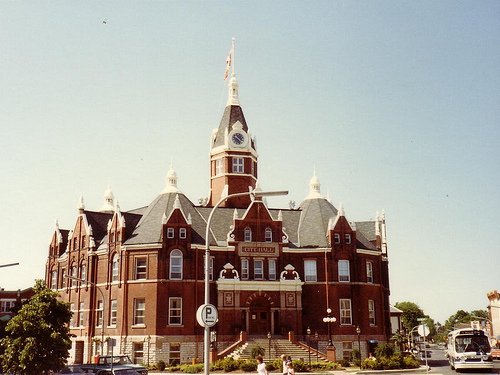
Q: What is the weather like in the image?
A: It is cloudless.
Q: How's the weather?
A: It is cloudless.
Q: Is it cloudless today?
A: Yes, it is cloudless.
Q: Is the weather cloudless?
A: Yes, it is cloudless.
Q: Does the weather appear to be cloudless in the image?
A: Yes, it is cloudless.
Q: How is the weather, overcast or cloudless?
A: It is cloudless.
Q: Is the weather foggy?
A: No, it is cloudless.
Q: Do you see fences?
A: No, there are no fences.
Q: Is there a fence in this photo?
A: No, there are no fences.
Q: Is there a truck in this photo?
A: Yes, there is a truck.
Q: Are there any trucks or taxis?
A: Yes, there is a truck.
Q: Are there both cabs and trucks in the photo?
A: No, there is a truck but no taxis.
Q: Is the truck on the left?
A: Yes, the truck is on the left of the image.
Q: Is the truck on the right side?
A: No, the truck is on the left of the image.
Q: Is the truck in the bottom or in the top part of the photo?
A: The truck is in the bottom of the image.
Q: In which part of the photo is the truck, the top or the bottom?
A: The truck is in the bottom of the image.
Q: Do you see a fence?
A: No, there are no fences.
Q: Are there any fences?
A: No, there are no fences.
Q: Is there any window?
A: Yes, there is a window.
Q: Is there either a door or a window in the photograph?
A: Yes, there is a window.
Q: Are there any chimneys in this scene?
A: No, there are no chimneys.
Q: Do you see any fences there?
A: No, there are no fences.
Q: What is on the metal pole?
A: The sign is on the pole.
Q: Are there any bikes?
A: No, there are no bikes.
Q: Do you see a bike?
A: No, there are no bikes.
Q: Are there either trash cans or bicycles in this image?
A: No, there are no bicycles or trash cans.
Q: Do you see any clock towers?
A: Yes, there is a clock tower.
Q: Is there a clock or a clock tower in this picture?
A: Yes, there is a clock tower.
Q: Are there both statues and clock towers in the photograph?
A: No, there is a clock tower but no statues.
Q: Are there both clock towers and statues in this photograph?
A: No, there is a clock tower but no statues.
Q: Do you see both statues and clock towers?
A: No, there is a clock tower but no statues.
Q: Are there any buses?
A: Yes, there is a bus.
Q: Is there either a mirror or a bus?
A: Yes, there is a bus.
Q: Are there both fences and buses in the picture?
A: No, there is a bus but no fences.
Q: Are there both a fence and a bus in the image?
A: No, there is a bus but no fences.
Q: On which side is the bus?
A: The bus is on the right of the image.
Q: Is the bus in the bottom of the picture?
A: Yes, the bus is in the bottom of the image.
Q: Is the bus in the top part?
A: No, the bus is in the bottom of the image.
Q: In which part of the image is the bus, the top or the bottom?
A: The bus is in the bottom of the image.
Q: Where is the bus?
A: The bus is on the road.